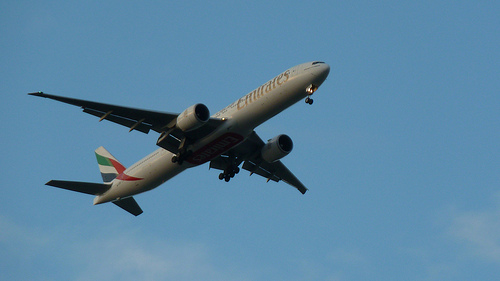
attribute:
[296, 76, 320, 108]
wheels — out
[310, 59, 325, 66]
window — black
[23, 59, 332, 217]
plane — red, white, blue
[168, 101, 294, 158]
holes — circular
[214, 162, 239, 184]
wheels — out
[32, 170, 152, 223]
tail — red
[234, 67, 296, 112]
lettering — red